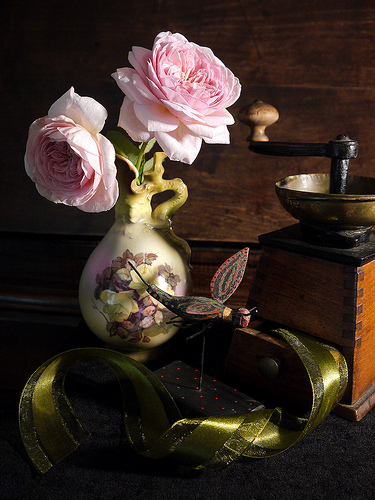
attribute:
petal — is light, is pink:
[129, 100, 181, 140]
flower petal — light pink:
[75, 177, 120, 211]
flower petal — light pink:
[154, 120, 203, 163]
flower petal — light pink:
[114, 94, 153, 142]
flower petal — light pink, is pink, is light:
[47, 86, 108, 132]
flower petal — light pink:
[202, 124, 230, 144]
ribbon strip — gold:
[17, 326, 348, 473]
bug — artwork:
[126, 247, 257, 330]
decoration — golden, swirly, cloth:
[82, 239, 200, 349]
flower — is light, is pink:
[105, 26, 245, 171]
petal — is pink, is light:
[151, 123, 204, 166]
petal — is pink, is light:
[65, 87, 110, 131]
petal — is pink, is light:
[118, 95, 148, 146]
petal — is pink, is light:
[83, 175, 119, 218]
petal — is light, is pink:
[128, 41, 148, 72]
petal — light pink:
[94, 131, 115, 190]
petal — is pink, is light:
[99, 68, 168, 119]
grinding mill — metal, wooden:
[241, 103, 371, 422]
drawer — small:
[224, 317, 348, 410]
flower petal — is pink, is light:
[133, 100, 176, 131]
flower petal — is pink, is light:
[95, 133, 115, 188]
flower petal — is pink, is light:
[154, 130, 201, 165]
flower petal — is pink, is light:
[198, 123, 229, 143]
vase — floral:
[70, 217, 196, 339]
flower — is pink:
[12, 83, 133, 231]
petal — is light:
[17, 84, 121, 211]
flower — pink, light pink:
[22, 83, 120, 214]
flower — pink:
[112, 30, 242, 167]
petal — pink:
[47, 85, 108, 133]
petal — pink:
[96, 134, 117, 190]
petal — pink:
[77, 179, 121, 213]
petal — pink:
[55, 124, 97, 156]